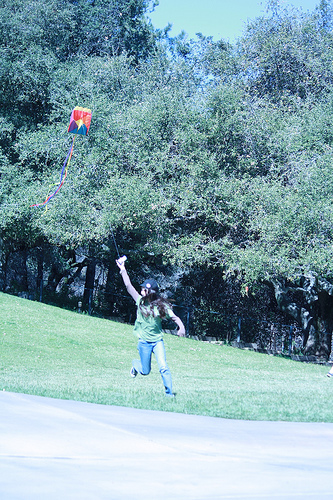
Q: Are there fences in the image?
A: No, there are no fences.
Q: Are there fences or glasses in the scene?
A: No, there are no fences or glasses.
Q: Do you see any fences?
A: No, there are no fences.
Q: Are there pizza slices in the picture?
A: No, there are no pizza slices.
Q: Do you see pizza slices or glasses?
A: No, there are no pizza slices or glasses.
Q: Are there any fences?
A: No, there are no fences.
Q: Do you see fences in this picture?
A: No, there are no fences.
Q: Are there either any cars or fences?
A: No, there are no fences or cars.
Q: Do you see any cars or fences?
A: No, there are no fences or cars.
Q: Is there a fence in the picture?
A: No, there are no fences.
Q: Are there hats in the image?
A: Yes, there is a hat.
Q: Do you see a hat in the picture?
A: Yes, there is a hat.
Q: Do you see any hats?
A: Yes, there is a hat.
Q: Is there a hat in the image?
A: Yes, there is a hat.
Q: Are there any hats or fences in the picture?
A: Yes, there is a hat.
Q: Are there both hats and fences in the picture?
A: No, there is a hat but no fences.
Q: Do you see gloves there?
A: No, there are no gloves.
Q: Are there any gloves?
A: No, there are no gloves.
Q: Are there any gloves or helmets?
A: No, there are no gloves or helmets.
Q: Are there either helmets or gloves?
A: No, there are no gloves or helmets.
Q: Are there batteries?
A: No, there are no batteries.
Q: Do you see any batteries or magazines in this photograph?
A: No, there are no batteries or magazines.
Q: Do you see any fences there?
A: No, there are no fences.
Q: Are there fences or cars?
A: No, there are no fences or cars.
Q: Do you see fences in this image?
A: No, there are no fences.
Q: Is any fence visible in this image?
A: No, there are no fences.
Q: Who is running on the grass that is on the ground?
A: The girl is running on the grass.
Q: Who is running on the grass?
A: The girl is running on the grass.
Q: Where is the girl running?
A: The girl is running on the grass.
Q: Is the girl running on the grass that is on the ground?
A: Yes, the girl is running on the grass.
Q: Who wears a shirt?
A: The girl wears a shirt.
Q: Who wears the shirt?
A: The girl wears a shirt.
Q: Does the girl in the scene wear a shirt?
A: Yes, the girl wears a shirt.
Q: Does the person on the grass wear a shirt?
A: Yes, the girl wears a shirt.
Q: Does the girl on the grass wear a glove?
A: No, the girl wears a shirt.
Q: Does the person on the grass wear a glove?
A: No, the girl wears a shirt.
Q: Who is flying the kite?
A: The girl is flying the kite.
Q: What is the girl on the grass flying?
A: The girl is flying the kite.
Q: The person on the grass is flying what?
A: The girl is flying the kite.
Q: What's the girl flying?
A: The girl is flying the kite.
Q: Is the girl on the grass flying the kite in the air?
A: Yes, the girl is flying the kite.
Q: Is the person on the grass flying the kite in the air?
A: Yes, the girl is flying the kite.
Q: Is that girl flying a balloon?
A: No, the girl is flying the kite.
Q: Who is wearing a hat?
A: The girl is wearing a hat.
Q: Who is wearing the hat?
A: The girl is wearing a hat.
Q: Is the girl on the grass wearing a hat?
A: Yes, the girl is wearing a hat.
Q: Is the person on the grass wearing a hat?
A: Yes, the girl is wearing a hat.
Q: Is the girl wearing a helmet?
A: No, the girl is wearing a hat.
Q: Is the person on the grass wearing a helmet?
A: No, the girl is wearing a hat.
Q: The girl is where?
A: The girl is on the grass.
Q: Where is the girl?
A: The girl is on the grass.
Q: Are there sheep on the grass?
A: No, there is a girl on the grass.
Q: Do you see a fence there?
A: No, there are no fences.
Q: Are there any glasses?
A: No, there are no glasses.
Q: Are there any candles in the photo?
A: No, there are no candles.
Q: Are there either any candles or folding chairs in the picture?
A: No, there are no candles or folding chairs.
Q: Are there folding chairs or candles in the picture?
A: No, there are no candles or folding chairs.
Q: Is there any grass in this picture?
A: Yes, there is grass.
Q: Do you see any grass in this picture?
A: Yes, there is grass.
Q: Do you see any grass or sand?
A: Yes, there is grass.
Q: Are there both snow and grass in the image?
A: No, there is grass but no snow.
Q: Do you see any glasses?
A: No, there are no glasses.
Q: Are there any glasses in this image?
A: No, there are no glasses.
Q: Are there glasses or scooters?
A: No, there are no glasses or scooters.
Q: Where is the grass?
A: The grass is on the ground.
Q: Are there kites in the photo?
A: Yes, there is a kite.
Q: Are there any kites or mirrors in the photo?
A: Yes, there is a kite.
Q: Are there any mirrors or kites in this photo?
A: Yes, there is a kite.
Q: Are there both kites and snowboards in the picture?
A: No, there is a kite but no snowboards.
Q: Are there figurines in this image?
A: No, there are no figurines.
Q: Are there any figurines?
A: No, there are no figurines.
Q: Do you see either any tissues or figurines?
A: No, there are no figurines or tissues.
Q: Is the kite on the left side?
A: Yes, the kite is on the left of the image.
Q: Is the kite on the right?
A: No, the kite is on the left of the image.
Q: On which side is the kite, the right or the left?
A: The kite is on the left of the image.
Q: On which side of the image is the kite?
A: The kite is on the left of the image.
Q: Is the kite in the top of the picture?
A: Yes, the kite is in the top of the image.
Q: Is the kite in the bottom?
A: No, the kite is in the top of the image.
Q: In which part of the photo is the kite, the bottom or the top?
A: The kite is in the top of the image.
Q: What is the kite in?
A: The kite is in the air.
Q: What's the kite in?
A: The kite is in the air.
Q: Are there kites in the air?
A: Yes, there is a kite in the air.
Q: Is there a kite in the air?
A: Yes, there is a kite in the air.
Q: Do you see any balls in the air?
A: No, there is a kite in the air.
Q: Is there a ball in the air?
A: No, there is a kite in the air.